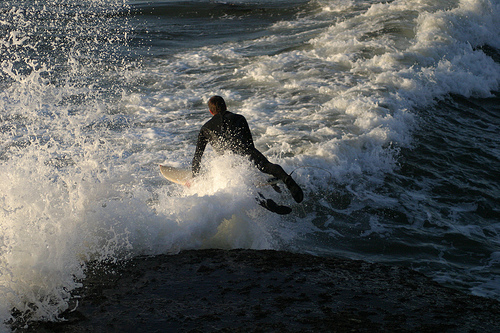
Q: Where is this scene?
A: Beach.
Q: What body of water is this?
A: Ocean.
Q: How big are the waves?
A: Very big.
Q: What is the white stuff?
A: Foam.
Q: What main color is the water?
A: Blue.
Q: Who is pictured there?
A: Surfer.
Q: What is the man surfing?
A: Waves.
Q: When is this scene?
A: Afternoon.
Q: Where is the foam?
A: In the water.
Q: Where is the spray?
A: In the air.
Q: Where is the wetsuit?
A: On the man.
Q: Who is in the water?
A: Surfer.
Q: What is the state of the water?
A: Waves breaking.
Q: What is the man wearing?
A: Black wetsuit.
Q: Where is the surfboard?
A: In the water.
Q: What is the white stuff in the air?
A: Ocean spray.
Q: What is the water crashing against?
A: Rock.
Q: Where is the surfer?
A: On the surfboard.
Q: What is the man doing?
A: Riding a surfboard.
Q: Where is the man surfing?
A: The ocean.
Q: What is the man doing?
A: Surfing.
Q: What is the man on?
A: A surfboard.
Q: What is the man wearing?
A: A black wetsuit.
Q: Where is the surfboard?
A: Under the man.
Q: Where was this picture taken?
A: In the ocean.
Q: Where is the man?
A: On the surfboard.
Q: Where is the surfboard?
A: In the water.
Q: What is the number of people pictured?
A: One.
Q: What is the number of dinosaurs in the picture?
A: Zero.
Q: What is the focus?
A: Surfer jumping wave.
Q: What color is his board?
A: White.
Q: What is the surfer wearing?
A: Wetsuit.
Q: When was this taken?
A: Daytime.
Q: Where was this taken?
A: Beach.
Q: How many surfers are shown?
A: 1.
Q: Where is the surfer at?
A: Top of the wave.